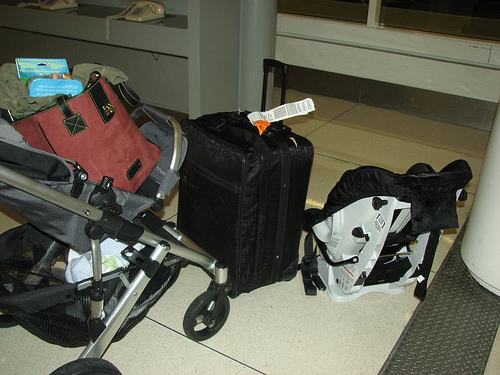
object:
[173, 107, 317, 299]
luggage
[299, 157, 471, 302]
car seat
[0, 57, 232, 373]
baby stroller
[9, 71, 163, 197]
bag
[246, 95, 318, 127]
luggage sticker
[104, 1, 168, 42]
corded telephone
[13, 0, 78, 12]
corded telephone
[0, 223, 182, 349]
basket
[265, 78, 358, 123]
floor tile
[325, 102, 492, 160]
floor tile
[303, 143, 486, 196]
floor tile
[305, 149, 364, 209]
floor tile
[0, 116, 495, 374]
floor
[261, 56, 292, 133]
handle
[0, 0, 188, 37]
shelf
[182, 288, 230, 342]
wheel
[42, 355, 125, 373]
wheel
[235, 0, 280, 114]
pole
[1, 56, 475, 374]
area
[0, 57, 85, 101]
goods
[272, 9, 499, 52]
window seal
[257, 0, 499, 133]
background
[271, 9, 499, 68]
windowsill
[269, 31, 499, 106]
base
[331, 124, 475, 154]
seam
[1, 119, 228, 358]
aluminum frame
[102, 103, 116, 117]
latch